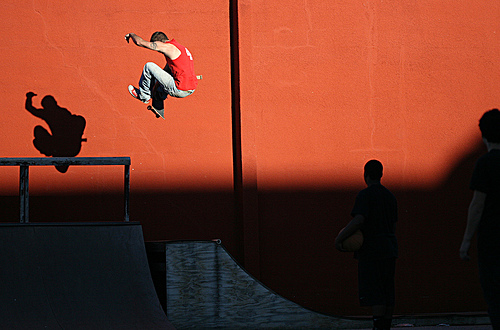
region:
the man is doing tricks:
[20, 18, 272, 253]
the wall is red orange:
[211, 22, 328, 173]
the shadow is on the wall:
[10, 76, 153, 248]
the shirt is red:
[154, 37, 207, 103]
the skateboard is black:
[144, 90, 190, 139]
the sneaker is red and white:
[114, 80, 153, 110]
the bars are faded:
[5, 150, 156, 224]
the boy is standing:
[453, 92, 498, 314]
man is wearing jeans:
[125, 54, 215, 126]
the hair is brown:
[137, 20, 181, 45]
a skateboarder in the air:
[65, 11, 257, 184]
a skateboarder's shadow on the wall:
[11, 60, 121, 199]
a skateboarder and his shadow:
[7, 2, 269, 214]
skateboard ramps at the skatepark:
[5, 63, 251, 328]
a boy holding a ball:
[309, 105, 434, 327]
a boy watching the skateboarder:
[307, 148, 449, 328]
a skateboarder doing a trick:
[74, 12, 253, 119]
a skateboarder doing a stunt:
[84, 5, 241, 142]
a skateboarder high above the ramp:
[93, 7, 264, 141]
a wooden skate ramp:
[155, 185, 289, 327]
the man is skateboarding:
[96, 11, 242, 131]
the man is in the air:
[119, 23, 221, 125]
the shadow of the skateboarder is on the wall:
[0, 63, 112, 194]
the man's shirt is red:
[155, 39, 231, 126]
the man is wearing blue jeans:
[119, 55, 191, 112]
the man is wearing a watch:
[102, 14, 142, 56]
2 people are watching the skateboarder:
[345, 106, 495, 325]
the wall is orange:
[1, 3, 487, 208]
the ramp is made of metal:
[1, 142, 147, 236]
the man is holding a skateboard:
[318, 112, 420, 328]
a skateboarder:
[114, 20, 247, 192]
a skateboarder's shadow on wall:
[16, 73, 104, 194]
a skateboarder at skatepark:
[4, 9, 282, 326]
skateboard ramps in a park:
[9, 128, 297, 328]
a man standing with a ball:
[276, 115, 422, 328]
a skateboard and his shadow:
[7, 7, 236, 195]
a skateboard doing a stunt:
[109, 13, 221, 141]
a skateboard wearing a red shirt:
[99, 9, 238, 184]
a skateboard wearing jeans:
[114, 24, 237, 123]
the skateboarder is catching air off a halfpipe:
[28, 20, 248, 292]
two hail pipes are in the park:
[6, 150, 477, 328]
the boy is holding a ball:
[334, 158, 402, 328]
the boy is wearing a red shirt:
[166, 25, 208, 93]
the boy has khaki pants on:
[138, 63, 195, 100]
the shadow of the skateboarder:
[16, 87, 93, 178]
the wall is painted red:
[13, 0, 499, 265]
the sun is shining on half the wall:
[6, 5, 490, 317]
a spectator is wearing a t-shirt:
[456, 99, 499, 317]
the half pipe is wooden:
[157, 236, 434, 328]